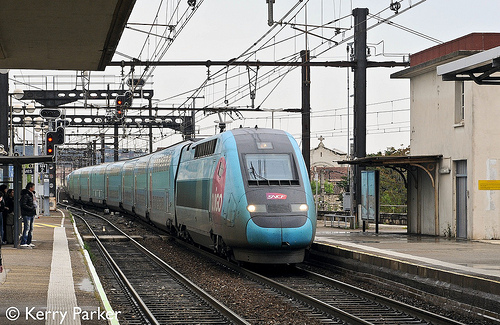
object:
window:
[110, 165, 121, 176]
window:
[137, 161, 147, 174]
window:
[81, 170, 88, 178]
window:
[241, 153, 300, 184]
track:
[121, 210, 466, 323]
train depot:
[1, 0, 498, 323]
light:
[48, 138, 53, 141]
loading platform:
[0, 209, 107, 325]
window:
[147, 170, 172, 195]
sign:
[360, 170, 377, 220]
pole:
[375, 169, 380, 233]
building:
[390, 32, 499, 239]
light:
[299, 204, 308, 211]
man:
[20, 183, 39, 247]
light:
[116, 97, 124, 118]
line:
[39, 200, 88, 320]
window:
[90, 173, 101, 185]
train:
[66, 125, 317, 265]